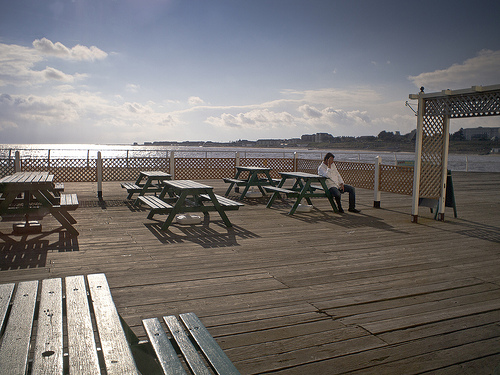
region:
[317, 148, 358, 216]
person sitting on picnic table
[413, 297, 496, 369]
brown planks on ground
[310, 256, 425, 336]
wooden planks on ground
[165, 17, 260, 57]
blue patch of sky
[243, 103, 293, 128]
white fluffy clouds in sky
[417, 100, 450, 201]
brown upright trellis on right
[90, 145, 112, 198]
white wooden support pole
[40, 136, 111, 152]
bright sun reflecting on water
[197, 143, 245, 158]
blue water in distance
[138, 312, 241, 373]
wooden picnic table bench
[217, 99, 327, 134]
these are the clouds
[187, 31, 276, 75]
this is the sky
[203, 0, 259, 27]
the sky is blue in color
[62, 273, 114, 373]
this is a bench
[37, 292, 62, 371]
the bench is wooden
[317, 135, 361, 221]
this is a man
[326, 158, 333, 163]
the man is light skinned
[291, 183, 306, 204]
the bench is green in color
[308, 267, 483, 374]
this is the ground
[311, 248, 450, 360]
the ground is wooden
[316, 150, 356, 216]
man sitting at table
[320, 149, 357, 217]
man sitting alone at table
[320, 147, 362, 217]
man wearing white shirt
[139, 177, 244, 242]
picnic table on deck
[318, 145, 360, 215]
man wearing blue jeans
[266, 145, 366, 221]
man sitting near water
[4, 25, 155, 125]
clouds in the sky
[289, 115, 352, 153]
buildings in the distance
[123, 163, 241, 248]
tables outside on deck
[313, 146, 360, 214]
man sitting outside on deck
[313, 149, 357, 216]
Guy in white shirt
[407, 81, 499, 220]
Entrance way to benches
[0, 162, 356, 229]
A group of benches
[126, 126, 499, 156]
Land in the background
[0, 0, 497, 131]
Clear sky filled with clouds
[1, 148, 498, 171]
The ocean in the background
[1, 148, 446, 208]
Gate around the bench area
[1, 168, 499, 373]
Wood plank flooring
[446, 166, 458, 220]
Sign in front of entrance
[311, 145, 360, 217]
Guy sitting on bench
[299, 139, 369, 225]
the man is sitting at the table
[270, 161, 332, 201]
the table is green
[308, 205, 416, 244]
shadow of the man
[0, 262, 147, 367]
the table is made of wood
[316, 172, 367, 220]
man is wearing jeans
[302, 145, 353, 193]
man is wearing a white shirt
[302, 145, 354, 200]
the shirt is long sleeves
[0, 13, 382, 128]
the sky is partly cloudy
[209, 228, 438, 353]
the floor is made of wood